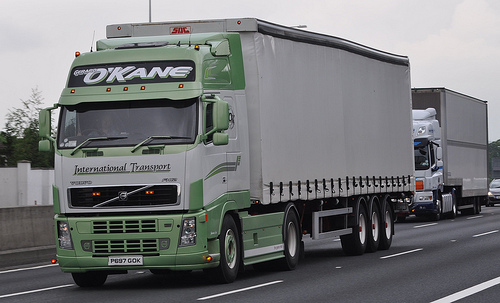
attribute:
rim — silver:
[219, 229, 249, 273]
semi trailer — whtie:
[37, 18, 417, 291]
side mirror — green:
[201, 96, 231, 146]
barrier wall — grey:
[0, 203, 59, 255]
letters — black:
[113, 257, 136, 262]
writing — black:
[112, 257, 140, 261]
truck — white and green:
[50, 17, 416, 287]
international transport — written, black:
[73, 161, 171, 174]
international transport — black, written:
[72, 160, 172, 173]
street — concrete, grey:
[1, 207, 498, 299]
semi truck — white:
[412, 84, 492, 220]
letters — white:
[72, 66, 192, 80]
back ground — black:
[64, 60, 198, 86]